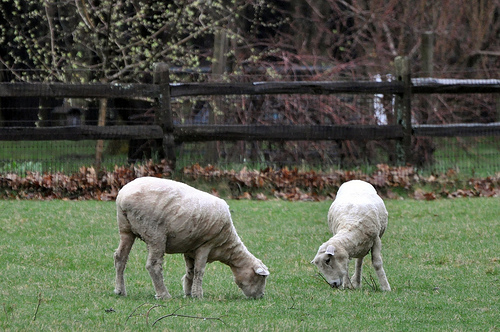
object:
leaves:
[114, 37, 141, 54]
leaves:
[412, 190, 427, 200]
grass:
[1, 137, 500, 330]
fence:
[2, 60, 500, 184]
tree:
[1, 0, 297, 170]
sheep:
[113, 176, 273, 302]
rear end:
[115, 176, 159, 229]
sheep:
[309, 178, 392, 292]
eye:
[324, 256, 332, 264]